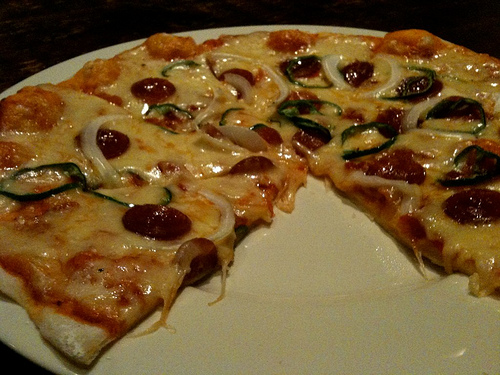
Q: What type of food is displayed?
A: Pizza.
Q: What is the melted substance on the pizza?
A: Cheese.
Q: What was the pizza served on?
A: Platter.